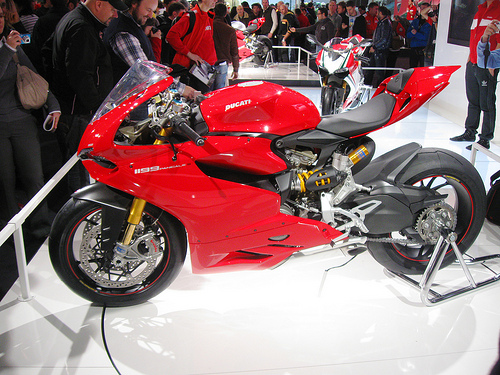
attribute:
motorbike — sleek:
[71, 57, 454, 281]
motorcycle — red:
[124, 78, 434, 243]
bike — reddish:
[80, 95, 437, 304]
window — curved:
[79, 50, 182, 138]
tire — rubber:
[374, 154, 480, 241]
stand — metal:
[396, 235, 496, 312]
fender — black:
[74, 187, 117, 217]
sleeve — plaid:
[104, 99, 154, 113]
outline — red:
[64, 226, 73, 267]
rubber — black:
[61, 204, 165, 319]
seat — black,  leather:
[324, 103, 384, 119]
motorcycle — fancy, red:
[40, 51, 434, 316]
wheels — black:
[63, 164, 444, 317]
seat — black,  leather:
[282, 74, 404, 163]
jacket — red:
[240, 100, 277, 104]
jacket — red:
[467, 108, 482, 121]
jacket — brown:
[271, 105, 310, 122]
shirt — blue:
[402, 12, 436, 58]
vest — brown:
[254, 5, 275, 35]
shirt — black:
[43, 8, 128, 133]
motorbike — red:
[45, 25, 495, 301]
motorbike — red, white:
[54, 36, 488, 316]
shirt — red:
[463, 6, 497, 68]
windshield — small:
[89, 54, 169, 124]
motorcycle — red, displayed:
[56, 20, 490, 309]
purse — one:
[10, 60, 52, 114]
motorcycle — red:
[37, 3, 495, 312]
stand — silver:
[413, 221, 478, 304]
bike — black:
[37, 14, 497, 321]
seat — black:
[321, 86, 399, 138]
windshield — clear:
[88, 52, 169, 117]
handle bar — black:
[161, 112, 211, 152]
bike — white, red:
[306, 24, 376, 116]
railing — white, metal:
[1, 168, 48, 308]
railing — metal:
[1, 137, 73, 306]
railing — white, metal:
[273, 39, 314, 77]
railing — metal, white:
[264, 39, 313, 75]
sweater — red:
[165, 4, 220, 70]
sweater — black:
[47, 4, 111, 116]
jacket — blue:
[407, 17, 434, 46]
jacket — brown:
[210, 20, 240, 65]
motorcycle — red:
[51, 54, 481, 298]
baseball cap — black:
[100, 2, 138, 20]